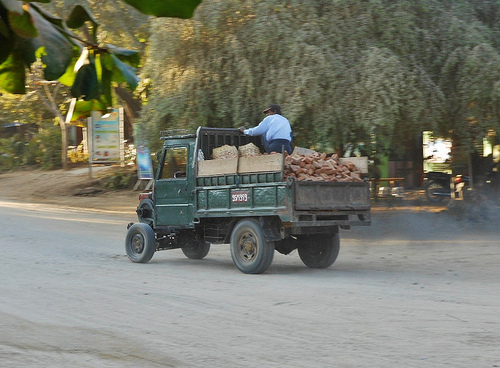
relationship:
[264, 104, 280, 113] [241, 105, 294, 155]
hat on man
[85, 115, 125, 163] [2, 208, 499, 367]
sign by road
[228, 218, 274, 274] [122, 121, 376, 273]
wheel on truck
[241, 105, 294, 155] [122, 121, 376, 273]
man in truck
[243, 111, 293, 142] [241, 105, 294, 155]
shirt on man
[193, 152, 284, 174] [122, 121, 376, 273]
board on truck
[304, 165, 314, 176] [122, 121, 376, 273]
wood in truck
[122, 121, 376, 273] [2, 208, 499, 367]
truck on road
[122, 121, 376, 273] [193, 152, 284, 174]
truck has a board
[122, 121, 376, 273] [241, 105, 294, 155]
truck with a man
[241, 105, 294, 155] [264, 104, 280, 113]
man with a hat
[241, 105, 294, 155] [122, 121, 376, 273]
man in back of truck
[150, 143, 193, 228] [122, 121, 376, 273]
door on truck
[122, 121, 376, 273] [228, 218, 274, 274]
truck with a wheel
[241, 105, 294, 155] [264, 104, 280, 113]
man wearing dark hat